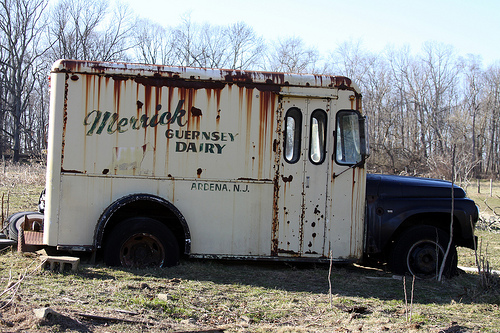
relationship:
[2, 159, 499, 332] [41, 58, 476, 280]
grass below truck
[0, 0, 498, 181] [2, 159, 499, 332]
trees are on grass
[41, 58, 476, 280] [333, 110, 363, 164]
truck has mirror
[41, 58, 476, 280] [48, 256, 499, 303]
truck has a shadow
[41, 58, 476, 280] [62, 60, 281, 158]
truck has rust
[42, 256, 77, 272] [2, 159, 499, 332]
block on grass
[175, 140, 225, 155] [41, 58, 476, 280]
dairy on truck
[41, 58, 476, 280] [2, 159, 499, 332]
truck in grass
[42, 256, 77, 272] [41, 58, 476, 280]
block behind truck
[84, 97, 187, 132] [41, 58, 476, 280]
merrick on truck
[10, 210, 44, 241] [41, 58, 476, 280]
tire behind truck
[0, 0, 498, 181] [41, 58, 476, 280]
trees behind truck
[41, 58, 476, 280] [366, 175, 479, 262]
truck has a front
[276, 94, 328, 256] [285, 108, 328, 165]
door has windows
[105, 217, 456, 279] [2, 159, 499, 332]
tires are stuck in grass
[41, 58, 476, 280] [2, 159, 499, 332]
truck on grass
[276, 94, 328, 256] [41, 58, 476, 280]
door on truck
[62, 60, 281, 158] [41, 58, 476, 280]
rust on truck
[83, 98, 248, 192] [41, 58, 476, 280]
letters are on truck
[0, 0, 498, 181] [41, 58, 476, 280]
trees are behind truck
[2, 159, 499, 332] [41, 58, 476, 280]
grass near truck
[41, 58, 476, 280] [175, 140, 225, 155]
truck for dairy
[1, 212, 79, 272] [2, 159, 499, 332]
junk on grass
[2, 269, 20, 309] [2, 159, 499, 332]
stick on grass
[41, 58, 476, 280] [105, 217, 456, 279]
truck has tires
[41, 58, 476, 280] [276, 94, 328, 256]
truck has door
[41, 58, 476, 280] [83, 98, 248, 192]
truck has letters